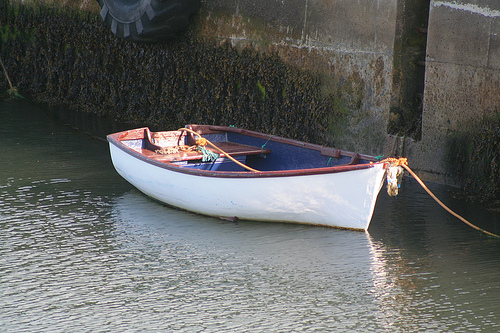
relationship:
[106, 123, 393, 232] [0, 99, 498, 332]
boat on water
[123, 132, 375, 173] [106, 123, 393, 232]
inside of boat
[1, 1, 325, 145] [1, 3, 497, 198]
seaweed on wall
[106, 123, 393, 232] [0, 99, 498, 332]
boat in water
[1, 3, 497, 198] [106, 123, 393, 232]
wall behind boat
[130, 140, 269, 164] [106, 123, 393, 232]
seat in boat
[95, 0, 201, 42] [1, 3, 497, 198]
tire hanging off wall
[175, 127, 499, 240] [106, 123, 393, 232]
rope across boat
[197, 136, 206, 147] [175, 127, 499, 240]
knot in rope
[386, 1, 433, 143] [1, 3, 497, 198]
drain in wall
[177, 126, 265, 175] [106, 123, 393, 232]
rope in boat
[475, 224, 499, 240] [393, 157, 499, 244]
moss on rope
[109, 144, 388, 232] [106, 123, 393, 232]
side of boat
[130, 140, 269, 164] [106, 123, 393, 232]
seat of boat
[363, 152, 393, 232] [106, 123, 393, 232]
tip of boat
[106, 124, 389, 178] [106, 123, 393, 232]
edge of boat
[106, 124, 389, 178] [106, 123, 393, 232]
edge around boat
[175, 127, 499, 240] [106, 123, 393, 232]
rope holding boat